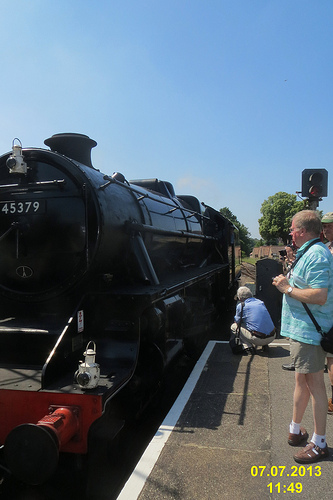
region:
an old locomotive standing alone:
[0, 124, 244, 476]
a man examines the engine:
[171, 270, 276, 368]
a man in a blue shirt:
[221, 279, 277, 360]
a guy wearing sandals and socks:
[269, 416, 328, 480]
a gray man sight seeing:
[199, 284, 278, 375]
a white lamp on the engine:
[63, 334, 131, 402]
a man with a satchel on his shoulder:
[209, 284, 276, 376]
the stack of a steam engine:
[23, 115, 124, 195]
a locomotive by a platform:
[7, 136, 324, 494]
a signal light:
[272, 156, 330, 236]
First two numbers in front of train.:
[0, 203, 16, 212]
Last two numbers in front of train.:
[24, 201, 40, 212]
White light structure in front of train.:
[7, 135, 25, 178]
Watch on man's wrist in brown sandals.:
[285, 283, 294, 295]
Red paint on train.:
[4, 390, 102, 478]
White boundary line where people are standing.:
[93, 329, 209, 498]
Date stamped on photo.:
[243, 460, 326, 482]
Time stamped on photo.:
[260, 479, 313, 499]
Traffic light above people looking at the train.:
[302, 169, 329, 201]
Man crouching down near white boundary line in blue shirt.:
[229, 271, 277, 361]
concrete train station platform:
[113, 338, 328, 497]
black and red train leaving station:
[0, 131, 244, 486]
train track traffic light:
[298, 166, 324, 207]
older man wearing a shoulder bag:
[227, 284, 269, 351]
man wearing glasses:
[269, 207, 328, 461]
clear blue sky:
[0, 0, 327, 243]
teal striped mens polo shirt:
[276, 235, 328, 341]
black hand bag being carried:
[228, 295, 240, 350]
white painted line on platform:
[115, 337, 287, 495]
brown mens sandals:
[286, 425, 327, 461]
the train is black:
[1, 127, 245, 469]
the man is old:
[266, 205, 330, 463]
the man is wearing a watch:
[268, 206, 332, 468]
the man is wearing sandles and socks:
[269, 206, 331, 464]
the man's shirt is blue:
[272, 206, 330, 464]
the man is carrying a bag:
[272, 206, 332, 465]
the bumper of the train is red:
[3, 335, 132, 458]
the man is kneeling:
[227, 281, 274, 355]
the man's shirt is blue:
[227, 282, 278, 358]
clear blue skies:
[171, 107, 293, 154]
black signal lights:
[289, 162, 329, 200]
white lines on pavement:
[136, 437, 158, 464]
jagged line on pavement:
[188, 433, 249, 453]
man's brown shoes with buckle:
[295, 441, 332, 465]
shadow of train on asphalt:
[221, 366, 255, 433]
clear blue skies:
[158, 48, 295, 138]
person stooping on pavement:
[227, 285, 274, 359]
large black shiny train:
[18, 128, 254, 397]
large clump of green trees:
[258, 186, 313, 244]